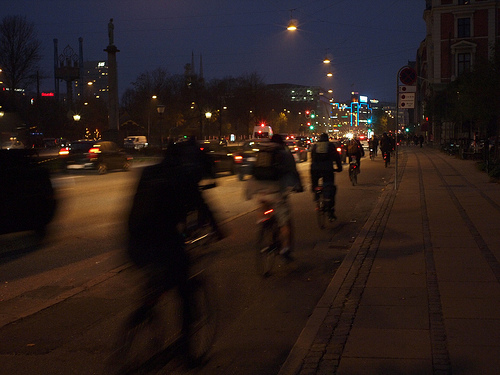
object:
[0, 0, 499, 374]
picture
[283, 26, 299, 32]
lights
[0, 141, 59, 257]
cars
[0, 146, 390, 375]
road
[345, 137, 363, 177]
people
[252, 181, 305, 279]
bikes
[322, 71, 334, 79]
lights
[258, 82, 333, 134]
building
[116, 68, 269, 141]
trees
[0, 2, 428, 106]
sky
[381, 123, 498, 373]
sidewalk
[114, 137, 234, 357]
people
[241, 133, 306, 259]
people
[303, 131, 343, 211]
people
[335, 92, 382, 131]
building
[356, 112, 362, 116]
lights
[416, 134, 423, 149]
people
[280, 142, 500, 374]
sidewalk